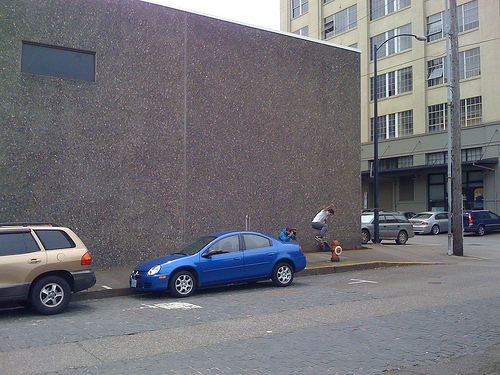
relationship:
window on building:
[369, 110, 411, 142] [281, 1, 500, 130]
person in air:
[307, 204, 339, 245] [316, 189, 339, 200]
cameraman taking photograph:
[277, 226, 299, 244] [292, 231, 301, 237]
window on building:
[369, 26, 412, 59] [281, 1, 500, 130]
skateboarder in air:
[307, 204, 339, 245] [316, 189, 339, 200]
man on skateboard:
[307, 204, 339, 245] [316, 237, 331, 251]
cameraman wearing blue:
[274, 224, 299, 244] [280, 230, 287, 240]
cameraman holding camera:
[277, 226, 299, 244] [293, 229, 300, 239]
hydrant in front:
[330, 238, 342, 262] [327, 235, 337, 243]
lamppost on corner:
[362, 28, 425, 246] [362, 238, 454, 263]